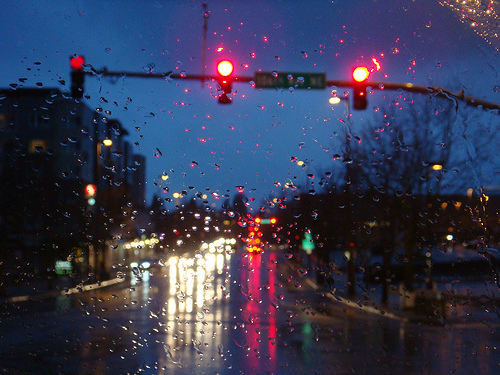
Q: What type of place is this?
A: It is a street.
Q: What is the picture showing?
A: It is showing a street.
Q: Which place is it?
A: It is a street.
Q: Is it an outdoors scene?
A: Yes, it is outdoors.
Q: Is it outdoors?
A: Yes, it is outdoors.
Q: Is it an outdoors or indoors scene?
A: It is outdoors.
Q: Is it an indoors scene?
A: No, it is outdoors.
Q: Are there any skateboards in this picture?
A: No, there are no skateboards.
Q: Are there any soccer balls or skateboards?
A: No, there are no skateboards or soccer balls.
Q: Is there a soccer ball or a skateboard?
A: No, there are no skateboards or soccer balls.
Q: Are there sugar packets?
A: No, there are no sugar packets.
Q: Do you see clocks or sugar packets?
A: No, there are no sugar packets or clocks.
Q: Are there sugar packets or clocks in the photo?
A: No, there are no sugar packets or clocks.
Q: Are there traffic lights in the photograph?
A: Yes, there is a traffic light.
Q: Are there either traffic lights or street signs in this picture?
A: Yes, there is a traffic light.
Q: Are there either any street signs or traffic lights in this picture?
A: Yes, there is a traffic light.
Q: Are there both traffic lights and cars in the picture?
A: Yes, there are both a traffic light and a car.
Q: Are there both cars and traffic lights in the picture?
A: Yes, there are both a traffic light and a car.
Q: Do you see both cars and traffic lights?
A: Yes, there are both a traffic light and a car.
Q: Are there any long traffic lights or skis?
A: Yes, there is a long traffic light.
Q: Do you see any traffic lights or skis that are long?
A: Yes, the traffic light is long.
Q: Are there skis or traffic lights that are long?
A: Yes, the traffic light is long.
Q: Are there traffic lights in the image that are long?
A: Yes, there is a long traffic light.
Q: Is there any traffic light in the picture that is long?
A: Yes, there is a traffic light that is long.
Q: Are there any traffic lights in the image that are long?
A: Yes, there is a traffic light that is long.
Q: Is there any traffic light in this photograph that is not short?
A: Yes, there is a long traffic light.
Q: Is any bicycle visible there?
A: No, there are no bicycles.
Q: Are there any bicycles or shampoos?
A: No, there are no bicycles or shampoos.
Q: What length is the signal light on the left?
A: The traffic light is long.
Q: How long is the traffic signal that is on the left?
A: The traffic light is long.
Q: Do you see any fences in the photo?
A: No, there are no fences.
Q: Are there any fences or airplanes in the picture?
A: No, there are no fences or airplanes.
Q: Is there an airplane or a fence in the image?
A: No, there are no fences or airplanes.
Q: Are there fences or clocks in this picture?
A: No, there are no fences or clocks.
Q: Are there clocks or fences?
A: No, there are no fences or clocks.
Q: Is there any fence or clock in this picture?
A: No, there are no fences or clocks.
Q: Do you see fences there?
A: No, there are no fences.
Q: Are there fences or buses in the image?
A: No, there are no fences or buses.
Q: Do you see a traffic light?
A: Yes, there is a traffic light.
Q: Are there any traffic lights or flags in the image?
A: Yes, there is a traffic light.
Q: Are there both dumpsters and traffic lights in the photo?
A: No, there is a traffic light but no dumpsters.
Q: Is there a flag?
A: No, there are no flags.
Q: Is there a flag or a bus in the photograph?
A: No, there are no flags or buses.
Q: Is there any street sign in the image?
A: Yes, there is a street sign.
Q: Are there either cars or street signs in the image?
A: Yes, there is a street sign.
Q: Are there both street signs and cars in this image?
A: Yes, there are both a street sign and a car.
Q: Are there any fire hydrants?
A: No, there are no fire hydrants.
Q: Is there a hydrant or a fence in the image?
A: No, there are no fire hydrants or fences.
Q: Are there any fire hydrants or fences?
A: No, there are no fire hydrants or fences.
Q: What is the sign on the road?
A: The sign is a street sign.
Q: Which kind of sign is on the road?
A: The sign is a street sign.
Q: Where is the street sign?
A: The street sign is on the road.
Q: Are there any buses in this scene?
A: No, there are no buses.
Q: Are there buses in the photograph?
A: No, there are no buses.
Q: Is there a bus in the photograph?
A: No, there are no buses.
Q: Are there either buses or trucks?
A: No, there are no buses or trucks.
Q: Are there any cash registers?
A: No, there are no cash registers.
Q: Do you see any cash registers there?
A: No, there are no cash registers.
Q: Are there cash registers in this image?
A: No, there are no cash registers.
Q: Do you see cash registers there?
A: No, there are no cash registers.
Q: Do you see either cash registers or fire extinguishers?
A: No, there are no cash registers or fire extinguishers.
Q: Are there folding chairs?
A: No, there are no folding chairs.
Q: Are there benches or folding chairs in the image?
A: No, there are no folding chairs or benches.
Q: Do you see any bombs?
A: No, there are no bombs.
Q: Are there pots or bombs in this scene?
A: No, there are no bombs or pots.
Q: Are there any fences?
A: No, there are no fences.